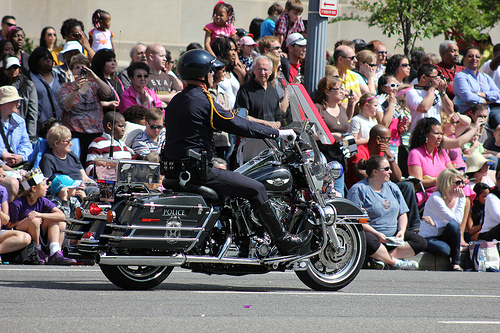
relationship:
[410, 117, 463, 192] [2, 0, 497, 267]
person in crowd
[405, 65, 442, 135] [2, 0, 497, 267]
person in crowd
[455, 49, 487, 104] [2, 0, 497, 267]
person in crowd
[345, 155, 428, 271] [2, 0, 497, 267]
person in crowd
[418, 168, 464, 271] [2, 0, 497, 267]
lady in crowd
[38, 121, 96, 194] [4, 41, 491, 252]
person in crowd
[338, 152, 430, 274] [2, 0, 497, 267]
person in crowd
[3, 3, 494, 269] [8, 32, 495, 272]
spectators on sidewalk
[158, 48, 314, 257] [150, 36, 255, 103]
man wearing helmet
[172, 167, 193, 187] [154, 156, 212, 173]
handcuffs attached to belt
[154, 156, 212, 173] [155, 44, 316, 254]
belt of officer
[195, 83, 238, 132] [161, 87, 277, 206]
rope on uniform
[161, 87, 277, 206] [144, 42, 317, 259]
uniform of police officer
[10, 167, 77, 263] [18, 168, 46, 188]
child wearing gold crown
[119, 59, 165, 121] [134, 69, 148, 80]
woman wearing sunglasses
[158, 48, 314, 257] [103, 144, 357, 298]
man on motorcycle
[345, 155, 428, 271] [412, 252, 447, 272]
person seated on curb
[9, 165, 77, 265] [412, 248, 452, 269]
child seated on curb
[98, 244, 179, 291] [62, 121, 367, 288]
rear tire of motorcycle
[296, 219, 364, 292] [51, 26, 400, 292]
front tire of motorcycle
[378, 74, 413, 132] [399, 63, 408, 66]
people wearing sunglasses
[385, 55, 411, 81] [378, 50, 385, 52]
people wearing sunglasses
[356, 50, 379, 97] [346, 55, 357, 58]
people wearing sunglasses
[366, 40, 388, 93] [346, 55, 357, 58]
people wearing sunglasses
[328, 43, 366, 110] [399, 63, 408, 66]
people wearing sunglasses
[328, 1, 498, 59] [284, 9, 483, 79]
tree in background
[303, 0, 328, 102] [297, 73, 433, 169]
column among seats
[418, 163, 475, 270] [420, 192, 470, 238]
lady wearing blouse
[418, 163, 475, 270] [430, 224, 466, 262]
lady wearing jeans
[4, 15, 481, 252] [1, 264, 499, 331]
crowd on road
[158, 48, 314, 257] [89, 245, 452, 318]
man driving road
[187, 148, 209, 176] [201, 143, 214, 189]
gun in holster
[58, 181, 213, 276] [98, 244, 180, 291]
saddlebags on rear tire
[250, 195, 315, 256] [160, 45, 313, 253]
black boot on man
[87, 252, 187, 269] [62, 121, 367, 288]
chrome exhaust on motorcycle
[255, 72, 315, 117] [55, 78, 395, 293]
windshield on motorcycle